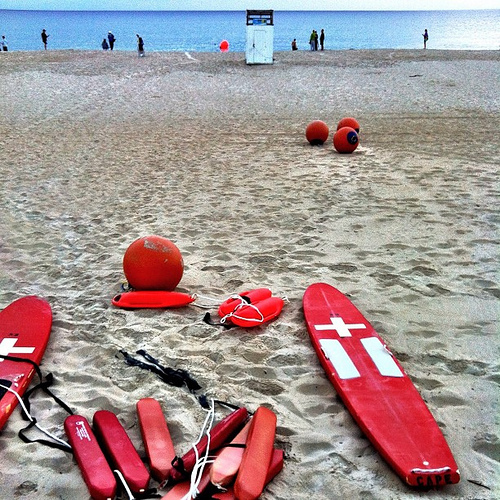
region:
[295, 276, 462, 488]
The surfboard is red.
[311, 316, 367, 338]
the cross is white.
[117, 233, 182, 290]
A ball on the beach.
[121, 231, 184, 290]
The ball is red.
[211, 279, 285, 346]
A red life jacket.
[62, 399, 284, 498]
A pile of floaties.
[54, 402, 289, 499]
The floaties are red.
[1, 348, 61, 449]
The straps are black and white.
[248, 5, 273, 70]
The lifeguard is not there.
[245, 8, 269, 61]
The lifeguard stand is white.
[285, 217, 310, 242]
Small patch of sand on the beach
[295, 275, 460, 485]
Red and white surfboard of lifeguard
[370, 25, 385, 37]
Small part of the blue ocean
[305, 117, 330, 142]
Red ball used by the lifeguard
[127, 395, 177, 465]
One of the red pads used by the lifeguard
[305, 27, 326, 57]
Group of pedestrians standing around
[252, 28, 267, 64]
White door in the background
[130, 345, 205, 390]
Black strap connected to the saving pad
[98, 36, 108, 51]
Lady bending down in the background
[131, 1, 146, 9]
A clear blue sky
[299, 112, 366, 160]
three red balls on beach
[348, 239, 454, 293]
foot prints in sand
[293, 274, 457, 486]
narrow red surfboard on sand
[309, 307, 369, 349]
white cross on red board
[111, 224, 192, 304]
red ball on sand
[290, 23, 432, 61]
people standing on shore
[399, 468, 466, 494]
word on edge of surfboard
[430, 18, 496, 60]
light reflection on water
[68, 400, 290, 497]
pile of floatation devices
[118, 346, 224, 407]
black straps in sand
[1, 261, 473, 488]
two life guard rafts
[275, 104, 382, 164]
three red balls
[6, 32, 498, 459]
tan and brown sand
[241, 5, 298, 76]
white and black observation deck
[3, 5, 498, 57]
blue ocean in background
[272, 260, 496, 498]
red and white lifeguard raft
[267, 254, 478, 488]
lifeguard raft with cross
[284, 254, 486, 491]
lifeguard raft labeled CAPE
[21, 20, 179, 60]
people standing on the beach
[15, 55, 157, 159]
tracks in the sand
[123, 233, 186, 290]
red rubber floating ball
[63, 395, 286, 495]
life preservers on beach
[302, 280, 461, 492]
rescue team's surfboard on beach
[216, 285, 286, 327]
life buoys used by lifeguards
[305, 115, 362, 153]
three floating buoys on beach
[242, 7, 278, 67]
lifeguard stand on beach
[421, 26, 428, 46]
person fishing from shore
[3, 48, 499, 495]
beach with life saving equipment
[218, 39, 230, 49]
red buoy floating in water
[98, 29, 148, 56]
people strolling on beach